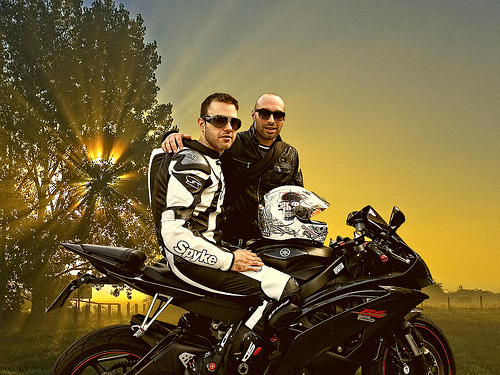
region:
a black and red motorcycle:
[46, 205, 456, 370]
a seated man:
[148, 91, 300, 373]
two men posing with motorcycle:
[48, 90, 468, 374]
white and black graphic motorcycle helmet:
[255, 182, 332, 245]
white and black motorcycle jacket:
[158, 143, 233, 271]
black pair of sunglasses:
[204, 114, 242, 130]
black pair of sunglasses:
[253, 107, 288, 123]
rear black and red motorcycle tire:
[46, 323, 181, 374]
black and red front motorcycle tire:
[370, 309, 457, 374]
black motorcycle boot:
[213, 321, 267, 374]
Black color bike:
[52, 230, 434, 327]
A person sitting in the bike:
[46, 85, 243, 317]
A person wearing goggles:
[205, 115, 244, 131]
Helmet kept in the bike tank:
[255, 180, 332, 249]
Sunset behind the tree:
[51, 131, 134, 207]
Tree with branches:
[13, 29, 63, 239]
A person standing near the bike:
[256, 99, 320, 180]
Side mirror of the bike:
[381, 200, 414, 235]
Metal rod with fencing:
[445, 291, 491, 321]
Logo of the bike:
[278, 245, 295, 259]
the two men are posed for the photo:
[46, 64, 452, 368]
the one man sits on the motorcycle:
[164, 56, 292, 373]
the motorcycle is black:
[63, 203, 497, 374]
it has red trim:
[350, 210, 460, 373]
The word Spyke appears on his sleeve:
[166, 229, 225, 271]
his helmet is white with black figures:
[252, 178, 332, 268]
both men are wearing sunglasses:
[200, 85, 297, 159]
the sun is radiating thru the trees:
[24, 85, 155, 244]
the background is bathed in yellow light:
[311, 59, 496, 299]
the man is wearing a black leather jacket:
[224, 88, 307, 190]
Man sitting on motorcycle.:
[145, 88, 295, 365]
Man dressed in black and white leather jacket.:
[148, 140, 240, 271]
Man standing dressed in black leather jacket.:
[227, 123, 307, 252]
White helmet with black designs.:
[251, 181, 329, 247]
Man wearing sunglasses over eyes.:
[201, 113, 243, 133]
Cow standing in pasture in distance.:
[451, 286, 482, 315]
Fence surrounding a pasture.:
[68, 295, 158, 325]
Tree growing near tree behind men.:
[6, 4, 171, 322]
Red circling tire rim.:
[370, 316, 457, 373]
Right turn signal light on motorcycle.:
[378, 199, 409, 242]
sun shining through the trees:
[65, 142, 132, 212]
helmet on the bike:
[255, 186, 330, 248]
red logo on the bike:
[350, 299, 385, 323]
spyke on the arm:
[165, 241, 222, 268]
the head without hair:
[249, 86, 290, 146]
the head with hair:
[200, 92, 240, 149]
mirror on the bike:
[385, 203, 410, 232]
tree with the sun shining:
[37, 61, 143, 228]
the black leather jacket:
[235, 135, 300, 229]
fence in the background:
[32, 284, 494, 325]